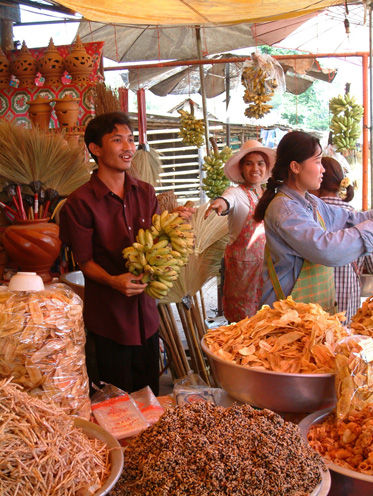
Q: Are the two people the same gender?
A: No, they are both male and female.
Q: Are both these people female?
A: No, they are both male and female.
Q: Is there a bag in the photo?
A: Yes, there is a bag.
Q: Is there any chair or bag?
A: Yes, there is a bag.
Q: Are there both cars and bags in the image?
A: No, there is a bag but no cars.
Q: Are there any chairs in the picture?
A: No, there are no chairs.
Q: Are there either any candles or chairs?
A: No, there are no chairs or candles.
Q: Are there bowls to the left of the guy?
A: Yes, there is a bowl to the left of the guy.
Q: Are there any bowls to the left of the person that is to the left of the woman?
A: Yes, there is a bowl to the left of the guy.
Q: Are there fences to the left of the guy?
A: No, there is a bowl to the left of the guy.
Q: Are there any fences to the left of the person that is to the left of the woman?
A: No, there is a bowl to the left of the guy.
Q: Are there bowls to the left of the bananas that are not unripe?
A: Yes, there is a bowl to the left of the bananas.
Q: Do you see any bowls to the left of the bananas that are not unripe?
A: Yes, there is a bowl to the left of the bananas.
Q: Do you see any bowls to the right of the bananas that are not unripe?
A: No, the bowl is to the left of the bananas.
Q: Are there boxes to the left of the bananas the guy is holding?
A: No, there is a bowl to the left of the bananas.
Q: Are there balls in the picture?
A: No, there are no balls.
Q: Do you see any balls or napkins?
A: No, there are no balls or napkins.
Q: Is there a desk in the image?
A: No, there are no desks.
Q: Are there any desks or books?
A: No, there are no desks or books.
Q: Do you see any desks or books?
A: No, there are no desks or books.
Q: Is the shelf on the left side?
A: Yes, the shelf is on the left of the image.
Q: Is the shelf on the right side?
A: No, the shelf is on the left of the image.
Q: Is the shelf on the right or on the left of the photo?
A: The shelf is on the left of the image.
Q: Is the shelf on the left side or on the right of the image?
A: The shelf is on the left of the image.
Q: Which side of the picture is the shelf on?
A: The shelf is on the left of the image.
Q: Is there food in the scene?
A: Yes, there is food.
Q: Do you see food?
A: Yes, there is food.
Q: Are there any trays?
A: No, there are no trays.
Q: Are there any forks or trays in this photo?
A: No, there are no trays or forks.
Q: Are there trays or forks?
A: No, there are no trays or forks.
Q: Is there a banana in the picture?
A: Yes, there are bananas.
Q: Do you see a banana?
A: Yes, there are bananas.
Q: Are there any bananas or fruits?
A: Yes, there are bananas.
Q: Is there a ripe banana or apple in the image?
A: Yes, there are ripe bananas.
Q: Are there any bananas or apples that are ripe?
A: Yes, the bananas are ripe.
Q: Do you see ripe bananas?
A: Yes, there are ripe bananas.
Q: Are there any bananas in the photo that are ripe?
A: Yes, there are bananas that are ripe.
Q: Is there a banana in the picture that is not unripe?
A: Yes, there are ripe bananas.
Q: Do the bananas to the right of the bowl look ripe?
A: Yes, the bananas are ripe.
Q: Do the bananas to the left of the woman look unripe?
A: No, the bananas are ripe.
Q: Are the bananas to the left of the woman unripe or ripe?
A: The bananas are ripe.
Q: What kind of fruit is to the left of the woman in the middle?
A: The fruits are bananas.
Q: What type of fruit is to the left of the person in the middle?
A: The fruits are bananas.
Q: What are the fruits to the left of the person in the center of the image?
A: The fruits are bananas.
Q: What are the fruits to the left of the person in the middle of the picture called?
A: The fruits are bananas.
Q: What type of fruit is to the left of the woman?
A: The fruits are bananas.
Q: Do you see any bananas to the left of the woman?
A: Yes, there are bananas to the left of the woman.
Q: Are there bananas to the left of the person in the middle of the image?
A: Yes, there are bananas to the left of the woman.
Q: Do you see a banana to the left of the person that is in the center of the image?
A: Yes, there are bananas to the left of the woman.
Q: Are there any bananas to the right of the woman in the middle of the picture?
A: No, the bananas are to the left of the woman.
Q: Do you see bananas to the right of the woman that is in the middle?
A: No, the bananas are to the left of the woman.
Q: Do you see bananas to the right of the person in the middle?
A: No, the bananas are to the left of the woman.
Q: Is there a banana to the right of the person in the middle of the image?
A: No, the bananas are to the left of the woman.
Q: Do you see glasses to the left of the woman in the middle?
A: No, there are bananas to the left of the woman.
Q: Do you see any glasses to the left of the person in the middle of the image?
A: No, there are bananas to the left of the woman.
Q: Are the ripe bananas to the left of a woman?
A: Yes, the bananas are to the left of a woman.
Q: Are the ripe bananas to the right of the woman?
A: No, the bananas are to the left of the woman.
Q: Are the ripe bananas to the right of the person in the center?
A: No, the bananas are to the left of the woman.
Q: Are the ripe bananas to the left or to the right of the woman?
A: The bananas are to the left of the woman.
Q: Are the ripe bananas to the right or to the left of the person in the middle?
A: The bananas are to the left of the woman.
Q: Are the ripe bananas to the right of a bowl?
A: Yes, the bananas are to the right of a bowl.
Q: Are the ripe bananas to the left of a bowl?
A: No, the bananas are to the right of a bowl.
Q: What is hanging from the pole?
A: The bananas are hanging from the pole.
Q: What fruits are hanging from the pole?
A: The fruits are bananas.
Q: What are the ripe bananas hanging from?
A: The bananas are hanging from the pole.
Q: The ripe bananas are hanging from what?
A: The bananas are hanging from the pole.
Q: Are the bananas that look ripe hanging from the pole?
A: Yes, the bananas are hanging from the pole.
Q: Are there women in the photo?
A: Yes, there is a woman.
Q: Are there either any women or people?
A: Yes, there is a woman.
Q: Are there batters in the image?
A: No, there are no batters.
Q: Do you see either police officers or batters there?
A: No, there are no batters or police officers.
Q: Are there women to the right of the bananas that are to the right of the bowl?
A: Yes, there is a woman to the right of the bananas.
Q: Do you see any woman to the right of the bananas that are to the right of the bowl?
A: Yes, there is a woman to the right of the bananas.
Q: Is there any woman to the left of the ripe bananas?
A: No, the woman is to the right of the bananas.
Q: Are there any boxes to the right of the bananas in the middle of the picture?
A: No, there is a woman to the right of the bananas.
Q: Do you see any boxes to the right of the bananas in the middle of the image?
A: No, there is a woman to the right of the bananas.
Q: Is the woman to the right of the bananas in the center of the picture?
A: Yes, the woman is to the right of the bananas.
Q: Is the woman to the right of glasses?
A: No, the woman is to the right of the bananas.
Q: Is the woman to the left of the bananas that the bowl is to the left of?
A: No, the woman is to the right of the bananas.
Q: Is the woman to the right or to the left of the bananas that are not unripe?
A: The woman is to the right of the bananas.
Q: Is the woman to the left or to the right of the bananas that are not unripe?
A: The woman is to the right of the bananas.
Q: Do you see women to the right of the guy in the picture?
A: Yes, there is a woman to the right of the guy.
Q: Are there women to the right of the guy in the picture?
A: Yes, there is a woman to the right of the guy.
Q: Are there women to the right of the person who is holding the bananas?
A: Yes, there is a woman to the right of the guy.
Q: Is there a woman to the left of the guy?
A: No, the woman is to the right of the guy.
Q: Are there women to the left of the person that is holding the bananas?
A: No, the woman is to the right of the guy.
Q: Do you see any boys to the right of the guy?
A: No, there is a woman to the right of the guy.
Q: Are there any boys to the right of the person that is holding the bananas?
A: No, there is a woman to the right of the guy.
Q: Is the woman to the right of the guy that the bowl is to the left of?
A: Yes, the woman is to the right of the guy.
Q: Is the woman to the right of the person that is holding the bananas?
A: Yes, the woman is to the right of the guy.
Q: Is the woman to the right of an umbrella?
A: No, the woman is to the right of the guy.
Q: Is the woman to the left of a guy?
A: No, the woman is to the right of a guy.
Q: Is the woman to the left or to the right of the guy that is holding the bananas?
A: The woman is to the right of the guy.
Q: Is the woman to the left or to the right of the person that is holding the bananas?
A: The woman is to the right of the guy.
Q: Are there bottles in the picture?
A: No, there are no bottles.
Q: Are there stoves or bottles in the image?
A: No, there are no bottles or stoves.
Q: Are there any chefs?
A: No, there are no chefs.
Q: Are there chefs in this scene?
A: No, there are no chefs.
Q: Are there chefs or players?
A: No, there are no chefs or players.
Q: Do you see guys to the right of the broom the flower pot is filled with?
A: Yes, there is a guy to the right of the broom.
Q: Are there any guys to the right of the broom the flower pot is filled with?
A: Yes, there is a guy to the right of the broom.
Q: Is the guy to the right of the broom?
A: Yes, the guy is to the right of the broom.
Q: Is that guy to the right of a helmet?
A: No, the guy is to the right of the broom.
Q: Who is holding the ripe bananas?
A: The guy is holding the bananas.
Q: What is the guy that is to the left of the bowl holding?
A: The guy is holding the bananas.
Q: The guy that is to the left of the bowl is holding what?
A: The guy is holding the bananas.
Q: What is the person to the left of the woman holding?
A: The guy is holding the bananas.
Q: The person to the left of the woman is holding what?
A: The guy is holding the bananas.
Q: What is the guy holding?
A: The guy is holding the bananas.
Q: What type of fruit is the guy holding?
A: The guy is holding the bananas.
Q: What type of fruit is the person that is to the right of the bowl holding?
A: The guy is holding the bananas.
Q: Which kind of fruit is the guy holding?
A: The guy is holding the bananas.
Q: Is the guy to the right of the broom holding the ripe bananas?
A: Yes, the guy is holding the bananas.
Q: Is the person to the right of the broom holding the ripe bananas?
A: Yes, the guy is holding the bananas.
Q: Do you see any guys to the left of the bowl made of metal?
A: Yes, there is a guy to the left of the bowl.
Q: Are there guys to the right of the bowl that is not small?
A: No, the guy is to the left of the bowl.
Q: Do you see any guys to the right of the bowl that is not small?
A: No, the guy is to the left of the bowl.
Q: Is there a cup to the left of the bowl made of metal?
A: No, there is a guy to the left of the bowl.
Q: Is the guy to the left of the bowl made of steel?
A: Yes, the guy is to the left of the bowl.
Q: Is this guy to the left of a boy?
A: No, the guy is to the left of the bowl.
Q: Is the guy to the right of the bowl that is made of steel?
A: No, the guy is to the left of the bowl.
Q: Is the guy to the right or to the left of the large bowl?
A: The guy is to the left of the bowl.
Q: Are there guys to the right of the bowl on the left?
A: Yes, there is a guy to the right of the bowl.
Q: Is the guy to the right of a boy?
A: No, the guy is to the right of the bowl.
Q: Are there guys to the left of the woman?
A: Yes, there is a guy to the left of the woman.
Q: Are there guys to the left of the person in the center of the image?
A: Yes, there is a guy to the left of the woman.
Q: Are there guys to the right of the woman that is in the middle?
A: No, the guy is to the left of the woman.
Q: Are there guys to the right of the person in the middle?
A: No, the guy is to the left of the woman.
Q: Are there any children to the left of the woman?
A: No, there is a guy to the left of the woman.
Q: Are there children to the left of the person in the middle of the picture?
A: No, there is a guy to the left of the woman.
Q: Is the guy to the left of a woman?
A: Yes, the guy is to the left of a woman.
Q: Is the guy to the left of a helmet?
A: No, the guy is to the left of a woman.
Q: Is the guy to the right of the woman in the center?
A: No, the guy is to the left of the woman.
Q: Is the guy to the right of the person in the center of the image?
A: No, the guy is to the left of the woman.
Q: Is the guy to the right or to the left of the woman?
A: The guy is to the left of the woman.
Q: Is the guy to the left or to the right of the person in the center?
A: The guy is to the left of the woman.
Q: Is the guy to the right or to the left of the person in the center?
A: The guy is to the left of the woman.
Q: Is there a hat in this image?
A: Yes, there is a hat.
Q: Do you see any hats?
A: Yes, there is a hat.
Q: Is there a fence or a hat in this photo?
A: Yes, there is a hat.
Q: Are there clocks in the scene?
A: No, there are no clocks.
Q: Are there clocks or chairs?
A: No, there are no clocks or chairs.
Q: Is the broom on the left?
A: Yes, the broom is on the left of the image.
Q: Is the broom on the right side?
A: No, the broom is on the left of the image.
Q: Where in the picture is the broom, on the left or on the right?
A: The broom is on the left of the image.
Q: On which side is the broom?
A: The broom is on the left of the image.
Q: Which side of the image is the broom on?
A: The broom is on the left of the image.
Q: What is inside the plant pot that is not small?
A: The broom is inside the plant pot.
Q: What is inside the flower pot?
A: The broom is inside the plant pot.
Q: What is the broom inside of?
A: The broom is inside the flower pot.